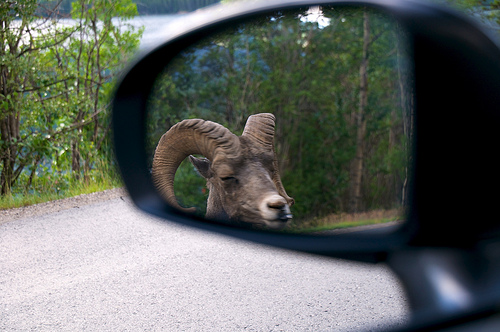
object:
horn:
[148, 118, 242, 216]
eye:
[215, 172, 237, 188]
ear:
[186, 147, 214, 182]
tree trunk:
[352, 8, 367, 216]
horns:
[239, 111, 282, 156]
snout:
[255, 189, 286, 215]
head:
[149, 112, 295, 238]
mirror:
[143, 8, 409, 235]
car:
[97, 0, 499, 331]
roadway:
[0, 185, 412, 332]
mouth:
[250, 211, 299, 232]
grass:
[0, 161, 119, 213]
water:
[0, 14, 180, 72]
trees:
[0, 0, 148, 210]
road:
[0, 182, 412, 331]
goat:
[148, 109, 298, 245]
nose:
[262, 194, 288, 215]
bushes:
[0, 0, 144, 209]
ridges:
[183, 114, 225, 141]